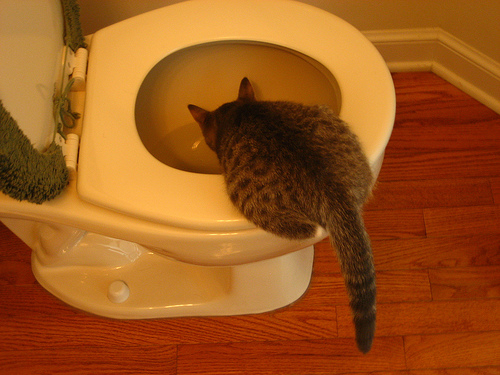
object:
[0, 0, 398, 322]
toilet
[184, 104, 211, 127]
ears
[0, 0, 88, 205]
lid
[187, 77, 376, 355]
cat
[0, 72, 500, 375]
floor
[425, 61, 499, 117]
white trim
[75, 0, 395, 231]
seat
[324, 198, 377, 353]
tail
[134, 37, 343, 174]
bowl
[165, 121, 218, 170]
water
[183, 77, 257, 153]
head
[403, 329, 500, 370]
wood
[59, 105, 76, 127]
string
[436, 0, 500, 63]
wall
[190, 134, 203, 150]
glare